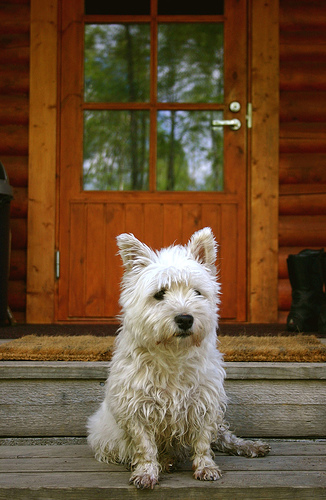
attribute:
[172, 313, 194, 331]
nose — tiny, black, small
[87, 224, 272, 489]
dog — White , alone , behind , small, furry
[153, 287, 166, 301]
eye — black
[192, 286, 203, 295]
eye — black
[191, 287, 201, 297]
eye — black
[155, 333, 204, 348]
fur — brown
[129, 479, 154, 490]
claws — small, orange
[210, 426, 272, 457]
leg — back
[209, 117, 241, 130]
handle — silver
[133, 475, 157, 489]
paw — Pink , dog's 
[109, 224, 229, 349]
face — dog's 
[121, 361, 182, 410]
fur — Brown 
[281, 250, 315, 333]
boots — Black 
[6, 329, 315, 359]
mat — Brown 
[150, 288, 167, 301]
eyes — dog's 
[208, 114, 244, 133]
handle — Metal 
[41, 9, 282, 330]
door — entrance 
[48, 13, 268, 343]
door — wooden , entrance 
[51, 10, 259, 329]
door — entrance , wood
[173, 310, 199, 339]
nose — black  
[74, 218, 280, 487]
dog — White , fluffy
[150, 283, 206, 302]
eyes — black  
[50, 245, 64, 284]
hinge — Silver 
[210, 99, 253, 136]
handle — Silver door 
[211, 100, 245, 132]
lock — Deadbolt 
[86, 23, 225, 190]
panes — reflecting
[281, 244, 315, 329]
boots — black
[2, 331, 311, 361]
mat — brown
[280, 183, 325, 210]
plank — wood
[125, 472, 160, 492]
paw — dirty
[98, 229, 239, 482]
dog — small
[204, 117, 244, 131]
handle — silver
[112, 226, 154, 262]
ear — white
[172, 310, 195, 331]
nose — black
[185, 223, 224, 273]
ear — white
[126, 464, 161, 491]
paw — white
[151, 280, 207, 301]
eyes — black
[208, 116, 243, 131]
handle — gold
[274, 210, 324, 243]
wood — plank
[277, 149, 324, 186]
wood — plank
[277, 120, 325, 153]
wood — plank